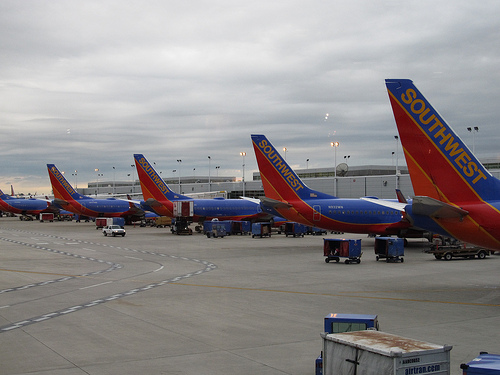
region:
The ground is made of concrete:
[78, 257, 253, 348]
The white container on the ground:
[312, 325, 458, 374]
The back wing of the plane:
[245, 125, 323, 195]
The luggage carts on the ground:
[317, 228, 367, 268]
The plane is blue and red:
[134, 153, 259, 230]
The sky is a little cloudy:
[36, 19, 376, 118]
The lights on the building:
[220, 134, 355, 164]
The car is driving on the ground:
[98, 215, 131, 240]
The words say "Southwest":
[255, 123, 312, 197]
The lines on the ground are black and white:
[15, 226, 221, 328]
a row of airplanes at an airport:
[6, 57, 486, 283]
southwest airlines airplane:
[246, 123, 426, 254]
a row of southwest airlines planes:
[27, 60, 494, 284]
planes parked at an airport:
[3, 82, 493, 334]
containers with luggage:
[303, 233, 416, 273]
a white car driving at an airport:
[97, 218, 157, 249]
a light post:
[321, 124, 344, 207]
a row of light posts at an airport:
[45, 150, 400, 198]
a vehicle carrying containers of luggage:
[311, 283, 485, 374]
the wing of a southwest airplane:
[246, 125, 308, 200]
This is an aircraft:
[238, 120, 438, 290]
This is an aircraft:
[356, 66, 489, 263]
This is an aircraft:
[126, 143, 296, 285]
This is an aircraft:
[48, 158, 163, 255]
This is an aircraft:
[3, 160, 108, 282]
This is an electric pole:
[235, 143, 247, 218]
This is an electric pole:
[325, 133, 340, 213]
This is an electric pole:
[303, 151, 313, 201]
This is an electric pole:
[204, 148, 213, 215]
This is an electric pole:
[90, 166, 103, 206]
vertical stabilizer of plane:
[378, 65, 496, 203]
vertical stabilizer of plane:
[245, 125, 311, 195]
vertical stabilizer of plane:
[125, 145, 180, 195]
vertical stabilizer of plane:
[40, 155, 80, 195]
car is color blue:
[315, 225, 365, 260]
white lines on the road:
[8, 230, 229, 348]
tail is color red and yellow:
[370, 70, 490, 193]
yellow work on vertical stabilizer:
[379, 68, 493, 195]